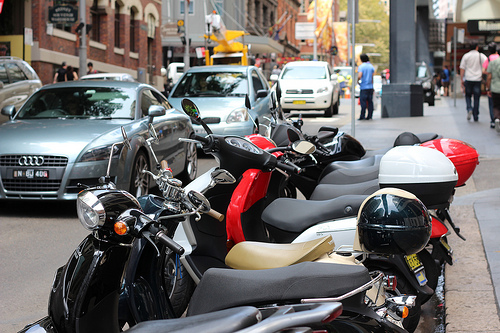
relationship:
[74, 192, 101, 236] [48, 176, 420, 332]
headlight on front of a scooter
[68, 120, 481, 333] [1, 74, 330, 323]
scooters parked on road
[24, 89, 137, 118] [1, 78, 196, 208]
windshield in front of a car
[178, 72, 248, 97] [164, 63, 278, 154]
windshield in front of a car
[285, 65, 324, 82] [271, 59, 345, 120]
windshield in front of a car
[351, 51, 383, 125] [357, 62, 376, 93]
man wearing a shirt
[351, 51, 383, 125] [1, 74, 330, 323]
man standing right of road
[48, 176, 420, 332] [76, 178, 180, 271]
scooter has handlebars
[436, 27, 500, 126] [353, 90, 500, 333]
people standing together on sidewalk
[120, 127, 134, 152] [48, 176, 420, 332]
sidemirror on a scooter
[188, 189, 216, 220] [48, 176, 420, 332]
sidemirror on a scooter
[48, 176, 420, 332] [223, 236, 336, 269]
scooter has a seat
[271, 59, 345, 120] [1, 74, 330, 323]
car on top of road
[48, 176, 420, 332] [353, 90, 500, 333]
scooter parked left of sidewalk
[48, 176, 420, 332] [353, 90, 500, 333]
scooter left of sidewalk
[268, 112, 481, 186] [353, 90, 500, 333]
scooter parked left of sidewalk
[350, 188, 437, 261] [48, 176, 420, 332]
motorcycle helmet on top of scooter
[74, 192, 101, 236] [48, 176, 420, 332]
headlight in front of a scooter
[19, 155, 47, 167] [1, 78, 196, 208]
logo in front of car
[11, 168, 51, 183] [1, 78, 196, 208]
license plate in front of a car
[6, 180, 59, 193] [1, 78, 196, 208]
grills are in front of a car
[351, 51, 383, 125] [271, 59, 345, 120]
man standing right of a car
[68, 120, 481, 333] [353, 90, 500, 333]
scooters are parked left of sidewalk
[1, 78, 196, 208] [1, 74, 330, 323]
car driving down road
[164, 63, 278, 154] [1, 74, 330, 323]
car driving down road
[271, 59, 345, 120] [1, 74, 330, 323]
car driving down road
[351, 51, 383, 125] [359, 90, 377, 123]
man wearing jeans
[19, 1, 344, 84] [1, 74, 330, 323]
buildings left of road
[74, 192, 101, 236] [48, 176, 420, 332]
headlight in front of scooter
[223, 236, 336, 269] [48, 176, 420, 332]
seat on top of scooter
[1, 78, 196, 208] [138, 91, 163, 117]
car has a window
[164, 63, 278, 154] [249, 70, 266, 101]
car has a window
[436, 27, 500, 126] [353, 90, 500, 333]
people are walking on sidewalk